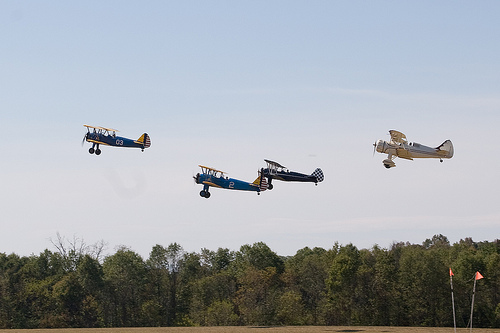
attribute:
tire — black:
[195, 187, 218, 203]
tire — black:
[361, 154, 402, 171]